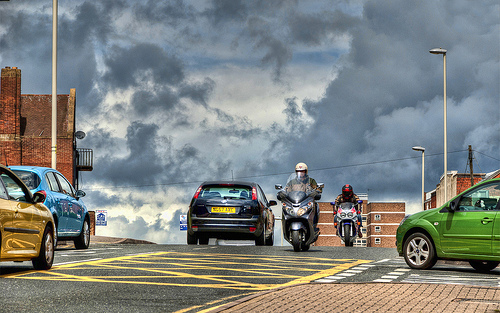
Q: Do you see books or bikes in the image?
A: Yes, there is a bike.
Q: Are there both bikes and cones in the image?
A: No, there is a bike but no cones.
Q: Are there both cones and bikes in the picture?
A: No, there is a bike but no cones.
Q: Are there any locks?
A: No, there are no locks.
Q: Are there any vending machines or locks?
A: No, there are no locks or vending machines.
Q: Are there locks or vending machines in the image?
A: No, there are no locks or vending machines.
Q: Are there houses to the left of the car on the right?
A: No, there is a bike to the left of the car.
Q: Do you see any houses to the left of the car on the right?
A: No, there is a bike to the left of the car.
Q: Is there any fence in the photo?
A: No, there are no fences.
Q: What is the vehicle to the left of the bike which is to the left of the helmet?
A: The vehicle is a car.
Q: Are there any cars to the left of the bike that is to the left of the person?
A: Yes, there is a car to the left of the bike.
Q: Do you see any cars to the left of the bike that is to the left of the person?
A: Yes, there is a car to the left of the bike.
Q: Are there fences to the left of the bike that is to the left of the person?
A: No, there is a car to the left of the bike.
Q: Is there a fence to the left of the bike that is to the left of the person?
A: No, there is a car to the left of the bike.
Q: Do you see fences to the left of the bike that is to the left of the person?
A: No, there is a car to the left of the bike.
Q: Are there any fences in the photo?
A: No, there are no fences.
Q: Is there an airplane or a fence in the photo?
A: No, there are no fences or airplanes.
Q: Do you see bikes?
A: Yes, there is a bike.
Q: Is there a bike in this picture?
A: Yes, there is a bike.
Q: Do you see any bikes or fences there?
A: Yes, there is a bike.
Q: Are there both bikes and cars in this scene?
A: Yes, there are both a bike and a car.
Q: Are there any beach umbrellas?
A: No, there are no beach umbrellas.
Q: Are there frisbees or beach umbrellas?
A: No, there are no beach umbrellas or frisbees.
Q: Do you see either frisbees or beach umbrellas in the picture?
A: No, there are no beach umbrellas or frisbees.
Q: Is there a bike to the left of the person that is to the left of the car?
A: Yes, there is a bike to the left of the person.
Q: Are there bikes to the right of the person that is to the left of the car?
A: No, the bike is to the left of the person.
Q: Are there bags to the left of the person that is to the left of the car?
A: No, there is a bike to the left of the person.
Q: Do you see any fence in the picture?
A: No, there are no fences.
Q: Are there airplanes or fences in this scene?
A: No, there are no fences or airplanes.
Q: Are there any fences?
A: No, there are no fences.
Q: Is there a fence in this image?
A: No, there are no fences.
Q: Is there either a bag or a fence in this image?
A: No, there are no fences or bags.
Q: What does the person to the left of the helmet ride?
A: The person rides a bike.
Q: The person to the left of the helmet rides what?
A: The person rides a bike.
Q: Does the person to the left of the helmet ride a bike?
A: Yes, the person rides a bike.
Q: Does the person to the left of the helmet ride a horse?
A: No, the person rides a bike.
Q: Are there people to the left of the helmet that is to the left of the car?
A: Yes, there is a person to the left of the helmet.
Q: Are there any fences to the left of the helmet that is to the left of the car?
A: No, there is a person to the left of the helmet.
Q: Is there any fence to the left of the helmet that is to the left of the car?
A: No, there is a person to the left of the helmet.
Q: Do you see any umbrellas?
A: No, there are no umbrellas.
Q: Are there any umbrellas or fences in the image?
A: No, there are no umbrellas or fences.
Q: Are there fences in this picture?
A: No, there are no fences.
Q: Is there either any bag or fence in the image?
A: No, there are no fences or bags.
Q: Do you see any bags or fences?
A: No, there are no fences or bags.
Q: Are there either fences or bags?
A: No, there are no fences or bags.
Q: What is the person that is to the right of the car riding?
A: The person is riding a bike.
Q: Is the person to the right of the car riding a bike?
A: Yes, the person is riding a bike.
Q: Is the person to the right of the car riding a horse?
A: No, the person is riding a bike.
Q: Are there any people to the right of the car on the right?
A: No, the person is to the left of the car.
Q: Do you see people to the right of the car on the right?
A: No, the person is to the left of the car.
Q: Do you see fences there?
A: No, there are no fences.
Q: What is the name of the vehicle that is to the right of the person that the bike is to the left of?
A: The vehicle is a car.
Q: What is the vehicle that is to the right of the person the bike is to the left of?
A: The vehicle is a car.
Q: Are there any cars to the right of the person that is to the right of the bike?
A: Yes, there is a car to the right of the person.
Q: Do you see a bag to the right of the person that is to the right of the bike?
A: No, there is a car to the right of the person.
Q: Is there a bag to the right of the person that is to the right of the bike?
A: No, there is a car to the right of the person.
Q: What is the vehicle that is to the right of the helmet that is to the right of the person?
A: The vehicle is a car.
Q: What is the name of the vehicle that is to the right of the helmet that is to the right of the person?
A: The vehicle is a car.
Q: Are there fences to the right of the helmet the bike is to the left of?
A: No, there is a car to the right of the helmet.